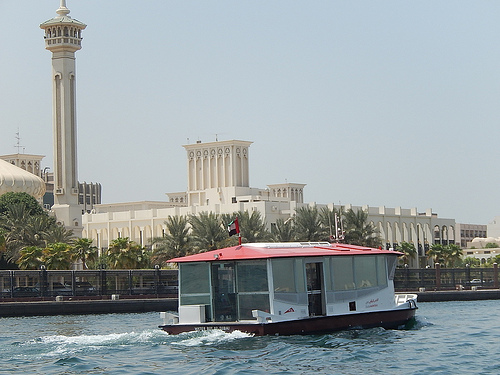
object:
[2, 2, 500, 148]
daylight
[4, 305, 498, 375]
water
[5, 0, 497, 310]
city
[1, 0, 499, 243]
nice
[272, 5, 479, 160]
sky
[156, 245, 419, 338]
boat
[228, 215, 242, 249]
flag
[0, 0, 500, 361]
photo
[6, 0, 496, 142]
afternoon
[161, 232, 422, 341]
houseboat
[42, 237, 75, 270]
trees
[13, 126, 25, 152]
antenna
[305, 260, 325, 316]
door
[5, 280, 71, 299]
cars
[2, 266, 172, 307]
lot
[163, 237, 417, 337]
ship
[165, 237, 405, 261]
rooftop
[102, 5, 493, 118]
skies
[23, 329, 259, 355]
waves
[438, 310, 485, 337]
ripples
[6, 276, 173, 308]
land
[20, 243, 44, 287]
tree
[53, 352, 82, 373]
waves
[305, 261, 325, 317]
side door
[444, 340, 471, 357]
waves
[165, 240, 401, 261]
roof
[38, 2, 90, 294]
tower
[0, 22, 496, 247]
background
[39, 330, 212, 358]
wake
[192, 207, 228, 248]
palm trees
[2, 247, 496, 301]
street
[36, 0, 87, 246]
tall building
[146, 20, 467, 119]
partially/clear sky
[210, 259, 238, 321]
an entrance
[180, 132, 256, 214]
tall/white structure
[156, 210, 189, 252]
palm trees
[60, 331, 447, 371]
body/moving water